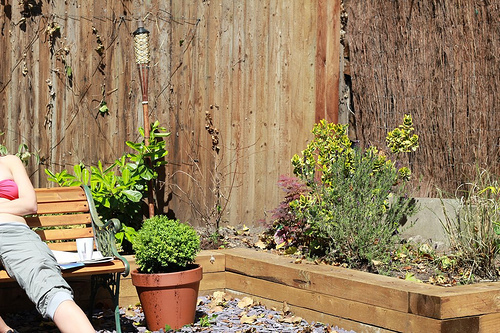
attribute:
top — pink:
[0, 175, 23, 203]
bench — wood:
[0, 178, 133, 332]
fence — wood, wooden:
[1, 0, 342, 229]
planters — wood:
[111, 243, 500, 331]